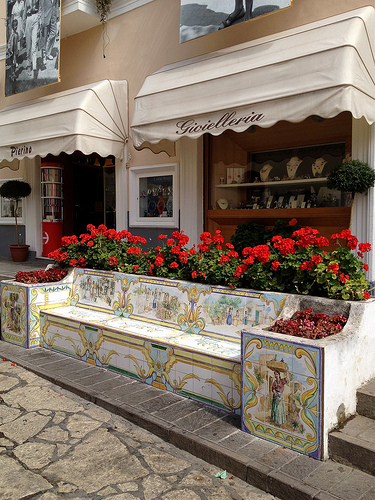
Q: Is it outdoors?
A: Yes, it is outdoors.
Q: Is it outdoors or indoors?
A: It is outdoors.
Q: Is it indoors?
A: No, it is outdoors.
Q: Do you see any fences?
A: No, there are no fences.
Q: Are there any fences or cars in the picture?
A: No, there are no fences or cars.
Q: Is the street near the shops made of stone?
A: Yes, the street is made of stone.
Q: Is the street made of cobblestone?
A: No, the street is made of stone.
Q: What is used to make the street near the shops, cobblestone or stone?
A: The street is made of stone.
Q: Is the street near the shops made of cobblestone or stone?
A: The street is made of stone.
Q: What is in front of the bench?
A: The street is in front of the bench.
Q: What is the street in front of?
A: The street is in front of the bench.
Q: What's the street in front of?
A: The street is in front of the bench.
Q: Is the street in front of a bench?
A: Yes, the street is in front of a bench.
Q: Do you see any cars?
A: No, there are no cars.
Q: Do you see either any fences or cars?
A: No, there are no cars or fences.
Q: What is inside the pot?
A: The tree is inside the pot.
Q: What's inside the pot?
A: The tree is inside the pot.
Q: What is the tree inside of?
A: The tree is inside the pot.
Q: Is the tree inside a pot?
A: Yes, the tree is inside a pot.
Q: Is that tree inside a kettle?
A: No, the tree is inside a pot.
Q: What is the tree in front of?
A: The tree is in front of the shops.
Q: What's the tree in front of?
A: The tree is in front of the shops.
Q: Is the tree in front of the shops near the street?
A: Yes, the tree is in front of the shops.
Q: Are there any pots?
A: Yes, there is a pot.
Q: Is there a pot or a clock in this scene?
A: Yes, there is a pot.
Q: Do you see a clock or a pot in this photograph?
A: Yes, there is a pot.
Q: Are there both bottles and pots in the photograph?
A: No, there is a pot but no bottles.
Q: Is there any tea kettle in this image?
A: No, there are no tea kettles.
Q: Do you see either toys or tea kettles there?
A: No, there are no tea kettles or toys.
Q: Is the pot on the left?
A: Yes, the pot is on the left of the image.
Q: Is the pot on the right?
A: No, the pot is on the left of the image.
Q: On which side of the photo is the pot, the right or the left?
A: The pot is on the left of the image.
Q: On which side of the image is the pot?
A: The pot is on the left of the image.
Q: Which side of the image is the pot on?
A: The pot is on the left of the image.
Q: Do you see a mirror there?
A: No, there are no mirrors.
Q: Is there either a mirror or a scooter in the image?
A: No, there are no mirrors or scooters.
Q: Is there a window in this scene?
A: Yes, there is a window.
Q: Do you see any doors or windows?
A: Yes, there is a window.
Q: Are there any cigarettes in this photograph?
A: No, there are no cigarettes.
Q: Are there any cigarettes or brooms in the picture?
A: No, there are no cigarettes or brooms.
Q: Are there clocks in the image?
A: No, there are no clocks.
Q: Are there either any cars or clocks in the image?
A: No, there are no clocks or cars.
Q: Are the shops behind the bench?
A: Yes, the shops are behind the bench.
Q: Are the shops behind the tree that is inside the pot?
A: Yes, the shops are behind the tree.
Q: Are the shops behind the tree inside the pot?
A: Yes, the shops are behind the tree.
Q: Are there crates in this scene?
A: No, there are no crates.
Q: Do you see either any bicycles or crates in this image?
A: No, there are no crates or bicycles.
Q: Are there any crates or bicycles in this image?
A: No, there are no crates or bicycles.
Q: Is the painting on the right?
A: Yes, the painting is on the right of the image.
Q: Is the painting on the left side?
A: No, the painting is on the right of the image.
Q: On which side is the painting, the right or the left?
A: The painting is on the right of the image.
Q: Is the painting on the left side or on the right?
A: The painting is on the right of the image.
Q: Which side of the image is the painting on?
A: The painting is on the right of the image.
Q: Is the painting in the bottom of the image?
A: Yes, the painting is in the bottom of the image.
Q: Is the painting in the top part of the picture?
A: No, the painting is in the bottom of the image.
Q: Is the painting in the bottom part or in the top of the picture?
A: The painting is in the bottom of the image.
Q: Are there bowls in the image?
A: No, there are no bowls.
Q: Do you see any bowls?
A: No, there are no bowls.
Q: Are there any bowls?
A: No, there are no bowls.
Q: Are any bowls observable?
A: No, there are no bowls.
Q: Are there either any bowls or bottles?
A: No, there are no bowls or bottles.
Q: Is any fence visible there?
A: No, there are no fences.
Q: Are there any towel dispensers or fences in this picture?
A: No, there are no fences or towel dispensers.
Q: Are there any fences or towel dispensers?
A: No, there are no fences or towel dispensers.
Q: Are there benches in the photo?
A: Yes, there is a bench.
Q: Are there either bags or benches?
A: Yes, there is a bench.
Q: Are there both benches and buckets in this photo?
A: No, there is a bench but no buckets.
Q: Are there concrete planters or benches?
A: Yes, there is a concrete bench.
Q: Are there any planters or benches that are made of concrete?
A: Yes, the bench is made of concrete.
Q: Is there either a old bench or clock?
A: Yes, there is an old bench.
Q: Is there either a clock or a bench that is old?
A: Yes, the bench is old.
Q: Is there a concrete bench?
A: Yes, there is a bench that is made of concrete.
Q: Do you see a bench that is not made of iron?
A: Yes, there is a bench that is made of concrete.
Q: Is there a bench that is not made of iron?
A: Yes, there is a bench that is made of concrete.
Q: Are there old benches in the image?
A: Yes, there is an old bench.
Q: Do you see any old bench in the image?
A: Yes, there is an old bench.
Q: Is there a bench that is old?
A: Yes, there is a bench that is old.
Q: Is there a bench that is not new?
A: Yes, there is a old bench.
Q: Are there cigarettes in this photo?
A: No, there are no cigarettes.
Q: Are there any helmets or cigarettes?
A: No, there are no cigarettes or helmets.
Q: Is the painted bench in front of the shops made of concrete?
A: Yes, the bench is made of concrete.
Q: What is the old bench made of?
A: The bench is made of concrete.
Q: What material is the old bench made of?
A: The bench is made of concrete.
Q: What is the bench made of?
A: The bench is made of concrete.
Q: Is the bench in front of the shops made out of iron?
A: No, the bench is made of concrete.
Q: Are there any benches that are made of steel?
A: No, there is a bench but it is made of concrete.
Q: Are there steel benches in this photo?
A: No, there is a bench but it is made of concrete.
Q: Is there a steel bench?
A: No, there is a bench but it is made of concrete.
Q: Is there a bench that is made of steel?
A: No, there is a bench but it is made of concrete.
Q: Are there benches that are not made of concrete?
A: No, there is a bench but it is made of concrete.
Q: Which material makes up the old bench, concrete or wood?
A: The bench is made of concrete.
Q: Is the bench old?
A: Yes, the bench is old.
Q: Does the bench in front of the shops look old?
A: Yes, the bench is old.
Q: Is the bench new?
A: No, the bench is old.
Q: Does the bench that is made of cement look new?
A: No, the bench is old.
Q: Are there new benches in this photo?
A: No, there is a bench but it is old.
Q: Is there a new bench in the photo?
A: No, there is a bench but it is old.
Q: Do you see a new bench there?
A: No, there is a bench but it is old.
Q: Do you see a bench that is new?
A: No, there is a bench but it is old.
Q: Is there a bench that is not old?
A: No, there is a bench but it is old.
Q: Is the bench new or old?
A: The bench is old.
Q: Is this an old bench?
A: Yes, this is an old bench.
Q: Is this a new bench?
A: No, this is an old bench.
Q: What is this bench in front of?
A: The bench is in front of the shops.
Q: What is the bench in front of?
A: The bench is in front of the shops.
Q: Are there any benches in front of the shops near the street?
A: Yes, there is a bench in front of the shops.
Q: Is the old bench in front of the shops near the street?
A: Yes, the bench is in front of the shops.